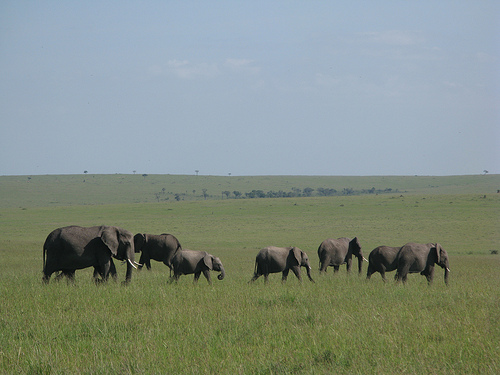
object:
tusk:
[124, 256, 141, 270]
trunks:
[122, 253, 139, 283]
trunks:
[302, 263, 317, 285]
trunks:
[440, 259, 454, 286]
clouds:
[53, 25, 485, 167]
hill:
[11, 159, 248, 213]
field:
[0, 173, 498, 373]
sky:
[12, 24, 457, 171]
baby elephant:
[168, 249, 225, 282]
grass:
[2, 175, 499, 372]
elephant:
[133, 230, 182, 276]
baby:
[391, 239, 452, 289]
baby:
[364, 246, 402, 281]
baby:
[317, 237, 366, 276]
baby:
[244, 244, 315, 287]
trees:
[164, 180, 415, 207]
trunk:
[212, 261, 227, 280]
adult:
[42, 222, 144, 284]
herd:
[42, 225, 451, 287]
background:
[0, 115, 491, 227]